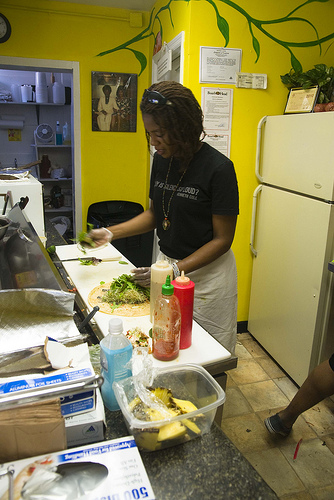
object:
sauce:
[150, 275, 182, 363]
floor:
[222, 319, 334, 498]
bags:
[0, 421, 67, 463]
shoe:
[264, 411, 294, 440]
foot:
[260, 408, 297, 439]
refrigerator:
[0, 166, 47, 234]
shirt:
[148, 146, 240, 263]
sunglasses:
[141, 84, 177, 107]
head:
[139, 75, 202, 157]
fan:
[51, 214, 69, 235]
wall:
[183, 0, 329, 335]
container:
[111, 361, 228, 452]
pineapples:
[170, 394, 202, 418]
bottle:
[168, 265, 194, 353]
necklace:
[161, 160, 188, 235]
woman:
[84, 81, 240, 357]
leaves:
[214, 12, 231, 49]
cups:
[19, 81, 34, 104]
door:
[245, 186, 333, 390]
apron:
[144, 250, 247, 362]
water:
[48, 163, 64, 180]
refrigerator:
[245, 99, 333, 396]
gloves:
[76, 226, 114, 251]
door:
[145, 39, 187, 124]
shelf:
[38, 144, 69, 182]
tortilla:
[85, 260, 158, 319]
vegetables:
[104, 272, 144, 304]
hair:
[140, 80, 204, 160]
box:
[0, 434, 157, 496]